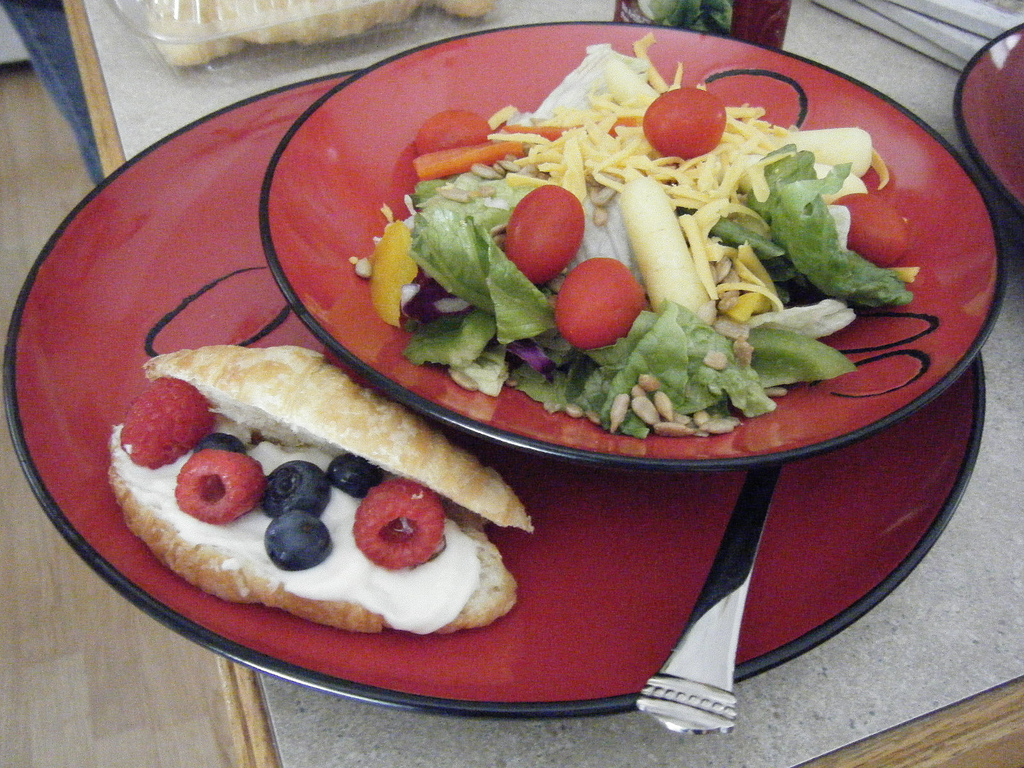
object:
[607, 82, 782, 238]
cheese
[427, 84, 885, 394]
salads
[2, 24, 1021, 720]
plate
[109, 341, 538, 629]
croissant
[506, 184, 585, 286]
tomato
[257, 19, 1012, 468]
plate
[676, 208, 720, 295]
cheese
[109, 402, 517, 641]
cream cheese